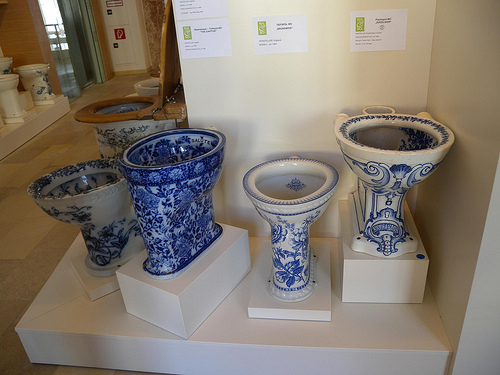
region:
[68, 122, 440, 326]
the vases are blue and white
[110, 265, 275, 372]
the stands are white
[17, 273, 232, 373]
the platform is white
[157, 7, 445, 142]
vase descriptions are on the wall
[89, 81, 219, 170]
a wooden toilet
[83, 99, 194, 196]
the toilet is on the stand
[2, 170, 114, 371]
the ground is made of tile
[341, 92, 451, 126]
a cup is behind the vase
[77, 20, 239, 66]
a door is by the wall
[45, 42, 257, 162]
the window has a shade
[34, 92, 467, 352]
Blue and white toilets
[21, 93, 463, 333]
toilets on display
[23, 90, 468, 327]
toilets in a museum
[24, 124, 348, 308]
toilet bowls without lids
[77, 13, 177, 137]
a lid on a toilet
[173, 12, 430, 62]
signs on the wall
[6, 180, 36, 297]
tile on the floor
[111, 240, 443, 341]
white pedastal bases with toilet bowls on them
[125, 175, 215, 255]
blue and white flowers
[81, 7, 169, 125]
an open toilet seat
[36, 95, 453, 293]
the toilets have designs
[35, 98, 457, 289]
the toilets are blue and white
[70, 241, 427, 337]
the toilets are on pedestals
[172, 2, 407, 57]
the wall has paper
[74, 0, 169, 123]
the toilet seat is made of wood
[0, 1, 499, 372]
the scene takes place indoors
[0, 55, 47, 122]
toilets in the distance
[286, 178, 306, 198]
the inside of toilet has design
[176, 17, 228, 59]
a piece of paper on the wall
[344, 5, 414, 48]
a piece of paper on the wall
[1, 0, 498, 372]
Fancy toilet store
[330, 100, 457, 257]
White and blue decorative toilet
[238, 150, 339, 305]
Smaller white and blue toilet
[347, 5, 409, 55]
White paper on the wall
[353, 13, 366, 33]
green decoration on white paper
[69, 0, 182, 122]
Large wood toilet seat and cover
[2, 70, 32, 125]
Plain white toilet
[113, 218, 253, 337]
Rectangular box base displays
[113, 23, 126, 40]
Red and white sign on the wall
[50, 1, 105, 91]
Silver elevator doors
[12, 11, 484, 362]
a variety of blue and white toilet bowls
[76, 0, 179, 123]
wooden toilet seat on top of toilet bowl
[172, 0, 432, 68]
papers on the wall provide info. about the bowls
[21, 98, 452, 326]
toilet bowls are on a platform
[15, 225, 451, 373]
large platform all the bowls are sitting on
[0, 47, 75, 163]
toilet bowels on display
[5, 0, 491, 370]
toilet bowls in a show room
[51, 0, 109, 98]
elevator doors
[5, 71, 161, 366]
beige floor tiles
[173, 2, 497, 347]
cream colored walls